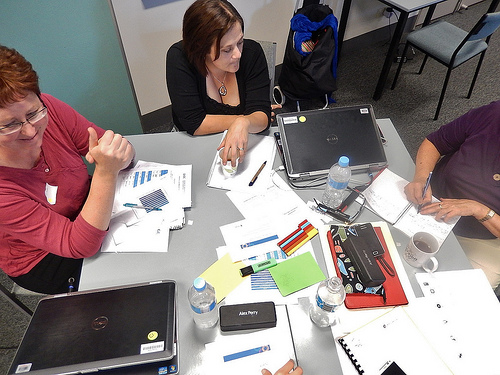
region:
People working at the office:
[13, 3, 497, 368]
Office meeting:
[8, 3, 489, 360]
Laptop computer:
[273, 103, 394, 178]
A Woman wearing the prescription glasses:
[0, 44, 56, 169]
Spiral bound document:
[331, 314, 428, 374]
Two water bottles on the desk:
[180, 270, 353, 346]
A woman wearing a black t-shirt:
[153, 0, 286, 142]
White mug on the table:
[405, 225, 435, 270]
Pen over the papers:
[122, 198, 168, 213]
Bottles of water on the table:
[190, 271, 346, 326]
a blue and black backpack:
[282, 4, 344, 104]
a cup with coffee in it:
[410, 228, 440, 270]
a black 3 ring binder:
[8, 277, 179, 371]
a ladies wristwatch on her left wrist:
[478, 205, 495, 227]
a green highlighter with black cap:
[240, 253, 280, 278]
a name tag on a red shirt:
[43, 178, 59, 208]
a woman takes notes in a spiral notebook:
[386, 164, 467, 242]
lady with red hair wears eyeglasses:
[0, 48, 49, 170]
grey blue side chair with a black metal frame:
[389, 0, 499, 116]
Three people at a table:
[5, 8, 490, 364]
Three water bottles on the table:
[167, 153, 379, 333]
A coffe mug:
[405, 220, 440, 270]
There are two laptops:
[16, 99, 398, 374]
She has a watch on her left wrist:
[475, 188, 497, 235]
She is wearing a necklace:
[198, 65, 250, 100]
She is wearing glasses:
[1, 108, 58, 140]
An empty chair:
[407, 13, 497, 105]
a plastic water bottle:
[305, 268, 352, 339]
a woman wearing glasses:
[0, 102, 56, 152]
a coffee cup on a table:
[399, 225, 446, 279]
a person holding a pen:
[407, 161, 444, 224]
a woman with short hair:
[192, 13, 257, 78]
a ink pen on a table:
[122, 189, 164, 219]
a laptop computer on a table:
[267, 96, 387, 181]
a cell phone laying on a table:
[357, 218, 379, 259]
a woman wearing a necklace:
[207, 68, 236, 103]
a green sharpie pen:
[235, 248, 275, 284]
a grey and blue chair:
[419, 26, 487, 63]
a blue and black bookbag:
[292, 8, 351, 110]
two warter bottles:
[186, 276, 352, 299]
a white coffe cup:
[406, 230, 441, 272]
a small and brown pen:
[246, 159, 273, 185]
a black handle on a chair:
[366, 2, 414, 102]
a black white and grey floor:
[362, 65, 374, 83]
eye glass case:
[221, 304, 281, 326]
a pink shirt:
[9, 177, 46, 238]